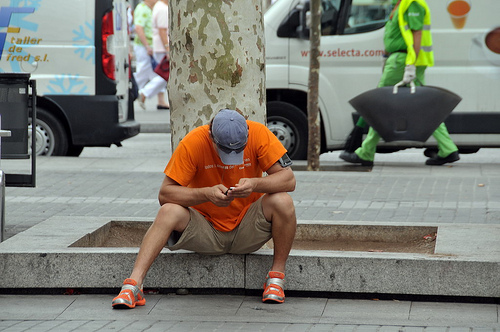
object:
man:
[111, 108, 297, 309]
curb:
[0, 215, 499, 304]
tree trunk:
[166, 0, 268, 177]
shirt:
[163, 120, 288, 232]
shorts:
[163, 192, 272, 256]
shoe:
[111, 277, 146, 309]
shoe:
[262, 268, 286, 303]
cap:
[211, 109, 247, 165]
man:
[339, 0, 460, 166]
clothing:
[353, 0, 458, 161]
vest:
[398, 0, 434, 67]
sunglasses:
[211, 137, 247, 155]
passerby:
[136, 0, 168, 111]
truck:
[0, 0, 140, 157]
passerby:
[132, 0, 168, 109]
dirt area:
[102, 226, 436, 254]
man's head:
[207, 108, 250, 158]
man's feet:
[111, 275, 146, 308]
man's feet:
[262, 263, 288, 304]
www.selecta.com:
[300, 49, 384, 59]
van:
[263, 0, 499, 160]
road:
[77, 132, 500, 162]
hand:
[203, 183, 234, 207]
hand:
[226, 177, 259, 197]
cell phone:
[224, 187, 236, 195]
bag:
[348, 77, 463, 144]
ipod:
[279, 152, 293, 168]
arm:
[252, 124, 296, 195]